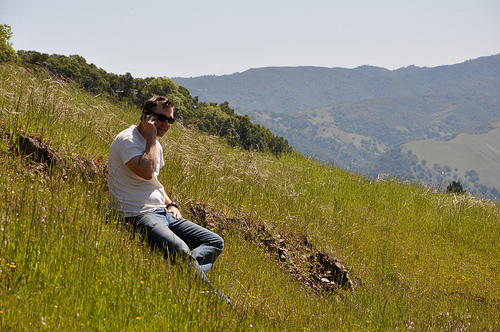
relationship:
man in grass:
[113, 97, 191, 244] [28, 233, 124, 305]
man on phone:
[113, 97, 191, 244] [141, 110, 157, 124]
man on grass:
[113, 97, 191, 244] [28, 233, 124, 305]